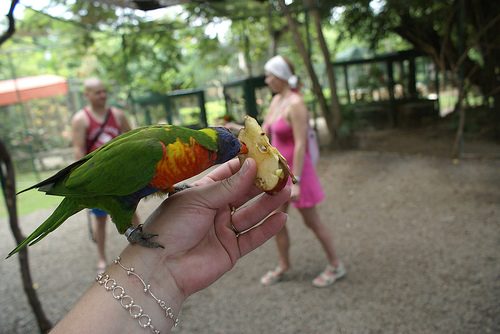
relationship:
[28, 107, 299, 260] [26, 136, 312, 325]
bird on hand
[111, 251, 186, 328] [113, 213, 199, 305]
bracelets on wrist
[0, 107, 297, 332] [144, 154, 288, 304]
bird sitting on hand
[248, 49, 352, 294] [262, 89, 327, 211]
woman wearing dress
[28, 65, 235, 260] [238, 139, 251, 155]
bird has beak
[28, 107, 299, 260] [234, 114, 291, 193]
bird eating fruit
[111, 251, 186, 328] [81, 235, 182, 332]
bracelets on wrist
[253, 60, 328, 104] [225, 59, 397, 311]
headband on woman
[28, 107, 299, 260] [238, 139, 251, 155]
bird has beak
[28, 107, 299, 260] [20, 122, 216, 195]
bird has feathers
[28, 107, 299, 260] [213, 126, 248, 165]
bird has head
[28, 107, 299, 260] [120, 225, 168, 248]
bird has talons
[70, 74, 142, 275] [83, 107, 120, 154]
man wearing shirt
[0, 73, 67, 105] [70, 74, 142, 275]
canopy behind man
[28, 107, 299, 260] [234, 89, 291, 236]
bird eating fruit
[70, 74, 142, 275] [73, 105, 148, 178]
man wearing shirt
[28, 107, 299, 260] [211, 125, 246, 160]
bird has head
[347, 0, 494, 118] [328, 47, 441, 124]
trees over structures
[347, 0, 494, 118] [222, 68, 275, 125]
trees over structures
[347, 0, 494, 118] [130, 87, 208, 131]
trees over structures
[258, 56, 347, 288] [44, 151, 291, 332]
person has hand